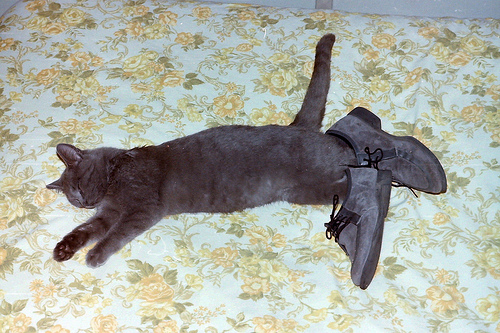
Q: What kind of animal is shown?
A: Cat.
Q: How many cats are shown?
A: One.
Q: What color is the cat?
A: Black.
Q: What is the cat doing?
A: Laying.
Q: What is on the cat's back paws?
A: Shoes.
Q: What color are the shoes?
A: Black.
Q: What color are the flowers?
A: Peach.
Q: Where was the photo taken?
A: On a bed in a home.